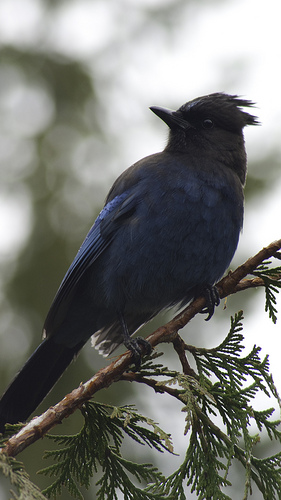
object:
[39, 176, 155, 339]
bird's wing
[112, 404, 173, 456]
needles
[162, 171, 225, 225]
feathers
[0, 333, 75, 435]
tail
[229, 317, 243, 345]
leaf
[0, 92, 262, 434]
bird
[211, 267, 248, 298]
branch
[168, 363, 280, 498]
leaves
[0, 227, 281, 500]
tree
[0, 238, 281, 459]
limb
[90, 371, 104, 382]
bark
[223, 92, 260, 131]
spiky feathers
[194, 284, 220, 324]
claw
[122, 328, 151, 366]
claw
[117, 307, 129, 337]
leg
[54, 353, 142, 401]
branch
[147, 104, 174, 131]
beak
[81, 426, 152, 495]
leaves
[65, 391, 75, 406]
bark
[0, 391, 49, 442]
branch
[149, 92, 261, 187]
head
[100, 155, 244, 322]
body